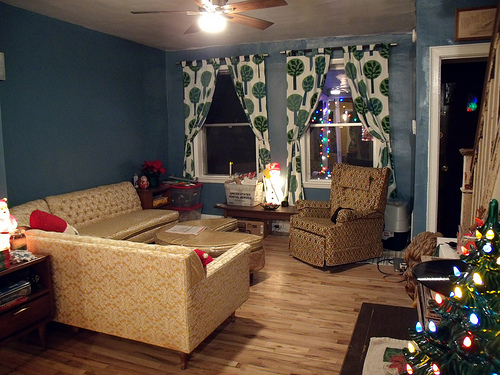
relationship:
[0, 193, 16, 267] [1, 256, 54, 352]
santa on table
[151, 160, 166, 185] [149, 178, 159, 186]
poinsetta in pot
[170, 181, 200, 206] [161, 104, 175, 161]
storage bins in corner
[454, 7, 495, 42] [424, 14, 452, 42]
framed picture on wall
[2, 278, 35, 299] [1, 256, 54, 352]
book inside table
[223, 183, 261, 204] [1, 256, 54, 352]
bin on table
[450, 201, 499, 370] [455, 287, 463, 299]
tree with lights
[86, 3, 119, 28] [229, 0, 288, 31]
ceiling has fan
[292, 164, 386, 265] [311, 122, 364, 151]
chair by window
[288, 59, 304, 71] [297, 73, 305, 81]
green and white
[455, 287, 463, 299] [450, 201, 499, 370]
lights on tree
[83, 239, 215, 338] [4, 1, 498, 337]
couch in room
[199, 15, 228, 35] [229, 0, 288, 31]
light and fan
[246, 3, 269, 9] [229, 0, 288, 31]
brown blades on fan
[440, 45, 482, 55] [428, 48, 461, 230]
white around door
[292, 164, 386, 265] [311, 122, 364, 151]
chair near window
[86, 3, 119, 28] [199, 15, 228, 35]
ceiling fan with light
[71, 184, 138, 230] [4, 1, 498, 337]
sofa in room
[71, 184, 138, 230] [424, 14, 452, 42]
sofa near wall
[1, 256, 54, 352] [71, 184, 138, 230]
table near sofa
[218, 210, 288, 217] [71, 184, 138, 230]
table near sofa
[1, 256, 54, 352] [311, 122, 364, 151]
table near window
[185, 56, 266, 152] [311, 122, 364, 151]
curtain on window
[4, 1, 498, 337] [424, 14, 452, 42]
room with wall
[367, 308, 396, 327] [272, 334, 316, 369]
rug on floor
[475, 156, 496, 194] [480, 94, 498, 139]
railing on stairway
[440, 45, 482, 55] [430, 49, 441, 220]
white door frame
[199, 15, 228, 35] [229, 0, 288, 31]
light on fan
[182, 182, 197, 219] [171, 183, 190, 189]
containers with covers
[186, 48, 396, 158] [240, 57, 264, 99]
curtains with trees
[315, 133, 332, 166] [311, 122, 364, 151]
lights though window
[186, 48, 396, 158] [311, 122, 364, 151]
curtains on window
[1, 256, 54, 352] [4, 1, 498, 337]
table in room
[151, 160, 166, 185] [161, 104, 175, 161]
plant in corner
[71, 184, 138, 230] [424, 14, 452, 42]
sofa against wall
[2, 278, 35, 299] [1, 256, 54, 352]
book under table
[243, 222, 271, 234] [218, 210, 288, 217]
box under table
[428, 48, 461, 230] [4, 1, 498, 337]
door in room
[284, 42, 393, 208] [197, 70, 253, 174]
curtains on window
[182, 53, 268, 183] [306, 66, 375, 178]
curtains on window